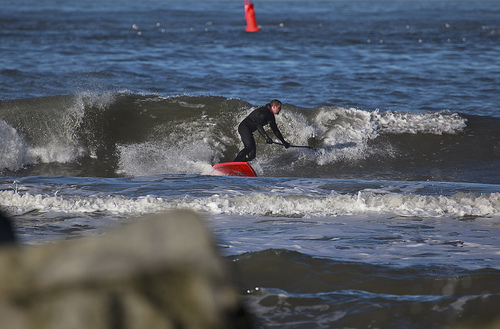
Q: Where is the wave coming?
A: Towards shore.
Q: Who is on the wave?
A: Surfer.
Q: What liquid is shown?
A: Water.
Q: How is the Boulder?
A: Blurry.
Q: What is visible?
A: Wakeboard.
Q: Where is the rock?
A: In foreground.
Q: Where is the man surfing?
A: Ocean.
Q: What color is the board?
A: Red.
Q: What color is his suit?
A: Black.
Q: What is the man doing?
A: Surfing.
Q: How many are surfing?
A: One.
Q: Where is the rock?
A: Left corner.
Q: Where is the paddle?
A: In the man's hands.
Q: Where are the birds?
A: Out in the water.